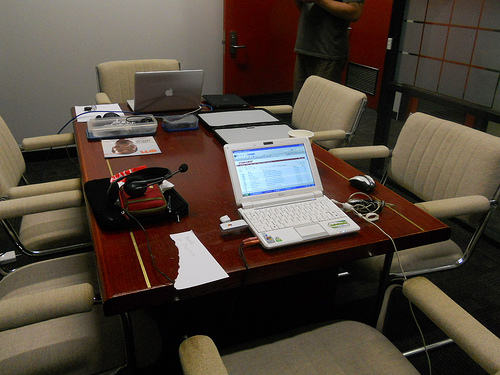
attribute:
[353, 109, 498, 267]
chair — empty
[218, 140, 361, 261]
laptop — white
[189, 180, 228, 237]
table — brown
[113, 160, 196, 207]
headphone — black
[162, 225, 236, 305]
paper — white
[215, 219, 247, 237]
usb — white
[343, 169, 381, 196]
mouse — cordless